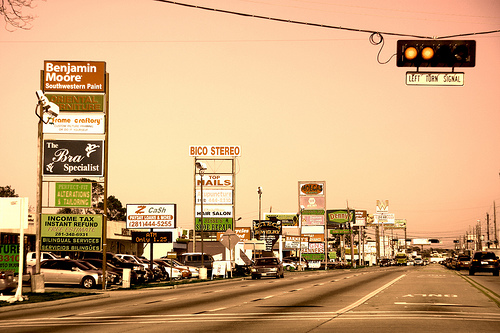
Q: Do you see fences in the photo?
A: No, there are no fences.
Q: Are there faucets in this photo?
A: No, there are no faucets.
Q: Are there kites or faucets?
A: No, there are no faucets or kites.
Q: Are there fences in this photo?
A: No, there are no fences.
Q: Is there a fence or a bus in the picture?
A: No, there are no fences or buses.